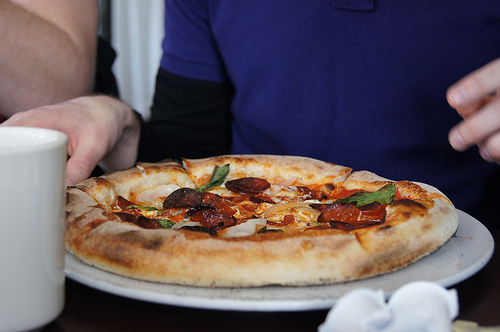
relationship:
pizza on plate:
[103, 179, 397, 258] [432, 249, 469, 276]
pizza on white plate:
[103, 179, 397, 258] [432, 249, 469, 276]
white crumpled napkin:
[406, 298, 439, 317] [343, 292, 453, 331]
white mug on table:
[406, 298, 439, 317] [78, 304, 129, 331]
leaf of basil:
[357, 190, 391, 202] [213, 166, 225, 184]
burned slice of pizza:
[102, 233, 161, 257] [103, 179, 397, 258]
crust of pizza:
[241, 245, 337, 270] [103, 179, 397, 258]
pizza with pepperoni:
[103, 179, 397, 258] [226, 179, 267, 194]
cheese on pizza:
[278, 183, 293, 198] [103, 179, 397, 258]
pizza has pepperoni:
[103, 179, 397, 258] [226, 179, 267, 194]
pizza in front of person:
[103, 179, 397, 258] [164, 1, 442, 139]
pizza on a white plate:
[103, 179, 397, 258] [432, 249, 469, 276]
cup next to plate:
[3, 125, 67, 330] [432, 249, 469, 276]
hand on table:
[67, 99, 132, 167] [78, 304, 129, 331]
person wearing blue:
[164, 1, 442, 139] [336, 21, 391, 62]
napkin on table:
[343, 292, 453, 331] [78, 304, 129, 331]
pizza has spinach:
[103, 179, 397, 258] [160, 219, 172, 228]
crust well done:
[241, 245, 337, 270] [400, 198, 420, 210]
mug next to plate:
[3, 125, 67, 330] [432, 249, 469, 276]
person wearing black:
[164, 1, 442, 139] [166, 95, 197, 117]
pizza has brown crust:
[103, 179, 397, 258] [241, 245, 337, 270]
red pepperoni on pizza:
[329, 207, 350, 220] [103, 179, 397, 258]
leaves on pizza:
[357, 190, 391, 202] [103, 179, 397, 258]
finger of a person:
[69, 150, 97, 176] [164, 1, 442, 139]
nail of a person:
[451, 136, 461, 147] [164, 1, 442, 139]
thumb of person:
[69, 150, 97, 176] [164, 1, 442, 139]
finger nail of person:
[66, 136, 109, 187] [164, 1, 442, 139]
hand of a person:
[67, 99, 132, 167] [164, 1, 442, 139]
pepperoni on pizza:
[226, 179, 267, 194] [103, 179, 397, 258]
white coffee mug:
[406, 298, 439, 317] [3, 125, 67, 330]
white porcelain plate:
[406, 298, 439, 317] [432, 249, 469, 276]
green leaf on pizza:
[216, 167, 223, 178] [103, 179, 397, 258]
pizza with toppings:
[103, 179, 397, 258] [164, 191, 237, 223]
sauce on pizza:
[171, 210, 182, 220] [103, 179, 397, 258]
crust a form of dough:
[241, 245, 337, 270] [134, 181, 157, 190]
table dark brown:
[78, 304, 129, 331] [148, 313, 200, 329]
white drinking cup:
[406, 298, 439, 317] [3, 125, 67, 330]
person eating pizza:
[164, 1, 442, 139] [103, 179, 397, 258]